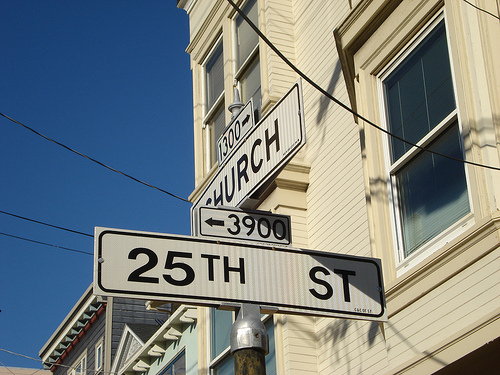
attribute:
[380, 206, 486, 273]
trim — white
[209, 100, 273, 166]
sign — street sign, black, white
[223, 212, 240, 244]
number — Black 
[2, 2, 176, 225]
sky — blue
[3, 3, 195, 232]
sky — clear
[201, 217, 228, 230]
arrow — Black 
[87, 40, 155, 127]
sky — clear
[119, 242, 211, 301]
number — Black 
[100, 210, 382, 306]
street sign — white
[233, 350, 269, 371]
post — sign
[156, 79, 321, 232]
sign — white, black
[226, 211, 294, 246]
number — 3900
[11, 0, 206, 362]
sky — blue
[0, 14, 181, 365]
sky — blue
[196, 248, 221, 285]
letter t — Black 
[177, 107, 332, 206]
sign — top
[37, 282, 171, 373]
building — gray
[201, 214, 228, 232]
arrow — black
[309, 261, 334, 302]
letter — Black 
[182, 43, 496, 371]
building — large, white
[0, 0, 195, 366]
sky — blue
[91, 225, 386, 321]
address sign — bottom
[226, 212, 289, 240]
number — Black 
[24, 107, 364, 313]
line — black, power line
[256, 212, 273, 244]
number — Black 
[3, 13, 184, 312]
sky — large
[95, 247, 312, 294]
number — Black 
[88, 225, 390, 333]
street sign — bottom, black, white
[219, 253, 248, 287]
letter — black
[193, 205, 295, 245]
street sign — black, white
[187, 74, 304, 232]
street sign — black, white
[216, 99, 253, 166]
street sign — black, white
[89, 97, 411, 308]
sign — address 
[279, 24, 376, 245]
siding — yellow